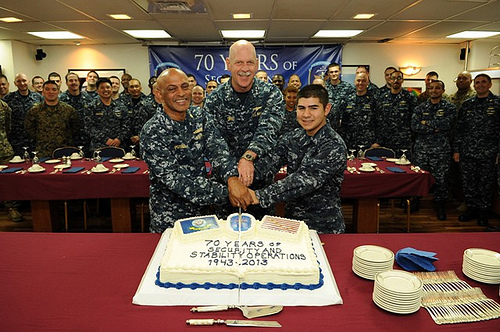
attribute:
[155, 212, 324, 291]
cake — white, cut, blue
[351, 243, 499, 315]
dishes — stacked, white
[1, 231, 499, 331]
table — red, set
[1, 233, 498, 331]
tablecloth — red, maroon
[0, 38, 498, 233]
men — military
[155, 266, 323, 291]
icing — blue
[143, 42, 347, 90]
banner — blue, blocked, large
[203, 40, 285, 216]
man — older, bald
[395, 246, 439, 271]
napkin — blue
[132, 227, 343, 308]
napkin — white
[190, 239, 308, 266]
lettering — blue